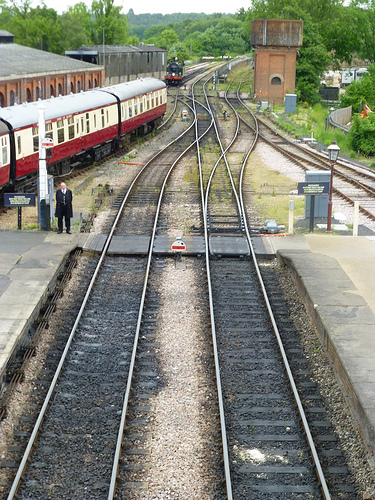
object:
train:
[0, 77, 166, 210]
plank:
[233, 484, 357, 493]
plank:
[221, 418, 306, 436]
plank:
[212, 412, 359, 431]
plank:
[4, 441, 152, 456]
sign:
[302, 182, 324, 194]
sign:
[40, 137, 53, 146]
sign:
[3, 192, 35, 205]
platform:
[287, 233, 375, 436]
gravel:
[0, 65, 374, 498]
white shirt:
[60, 188, 66, 194]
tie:
[219, 327, 275, 332]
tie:
[219, 309, 266, 315]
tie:
[218, 299, 258, 306]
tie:
[219, 317, 265, 323]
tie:
[218, 287, 256, 295]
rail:
[0, 53, 375, 500]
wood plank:
[219, 325, 269, 331]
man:
[55, 181, 73, 234]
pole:
[37, 97, 54, 229]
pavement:
[0, 226, 77, 366]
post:
[327, 138, 341, 233]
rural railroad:
[1, 24, 168, 85]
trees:
[7, 1, 374, 101]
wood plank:
[205, 385, 323, 402]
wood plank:
[209, 370, 320, 397]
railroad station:
[2, 0, 373, 498]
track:
[190, 54, 320, 494]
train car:
[161, 52, 186, 91]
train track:
[9, 77, 375, 500]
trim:
[11, 155, 55, 171]